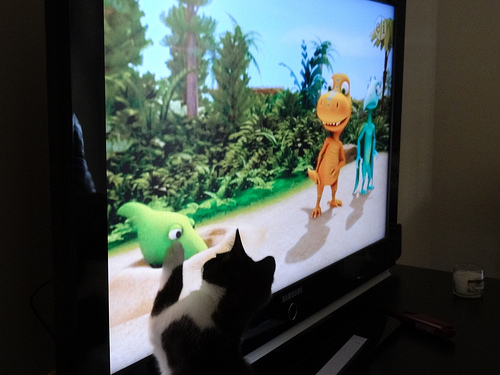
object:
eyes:
[340, 80, 351, 97]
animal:
[305, 72, 353, 221]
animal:
[114, 200, 209, 269]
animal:
[350, 75, 381, 196]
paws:
[163, 243, 184, 266]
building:
[249, 86, 284, 96]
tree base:
[185, 36, 199, 121]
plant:
[207, 21, 259, 134]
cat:
[145, 226, 277, 375]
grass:
[237, 186, 265, 209]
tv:
[66, 0, 407, 375]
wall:
[433, 3, 500, 222]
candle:
[451, 268, 484, 296]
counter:
[340, 264, 500, 374]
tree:
[103, 0, 156, 72]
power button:
[286, 301, 300, 322]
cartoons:
[105, 0, 394, 375]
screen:
[100, 0, 397, 375]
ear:
[221, 227, 247, 254]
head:
[199, 226, 277, 310]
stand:
[448, 265, 486, 300]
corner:
[395, 248, 406, 259]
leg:
[148, 244, 185, 324]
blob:
[71, 115, 95, 191]